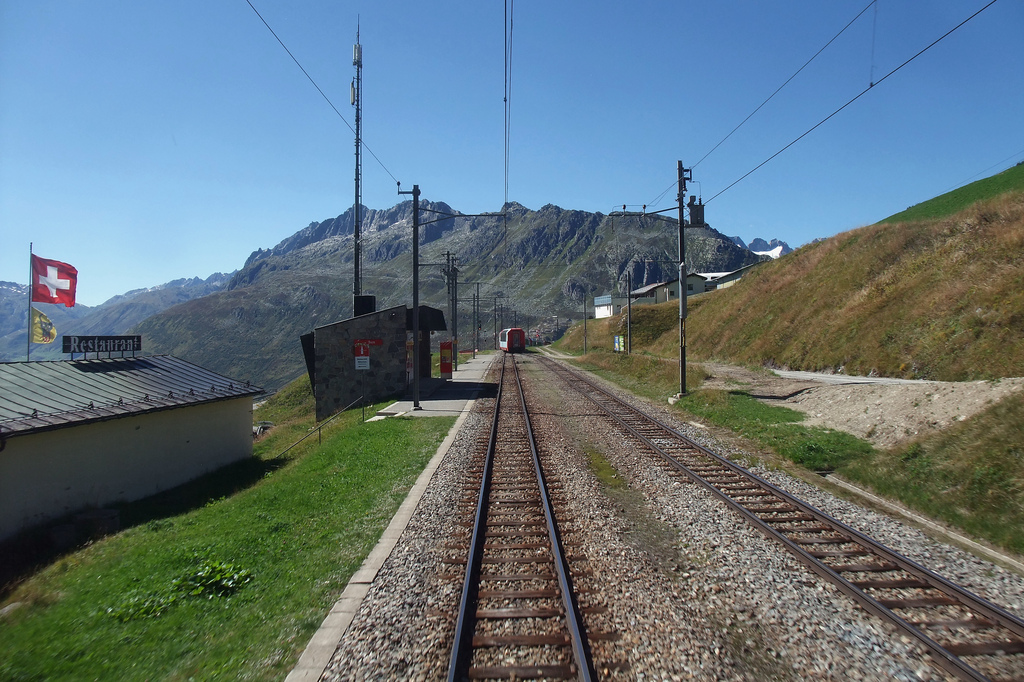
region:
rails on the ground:
[398, 359, 948, 669]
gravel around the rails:
[337, 371, 992, 681]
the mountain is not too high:
[107, 160, 759, 424]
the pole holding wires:
[650, 140, 721, 401]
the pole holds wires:
[324, 17, 392, 302]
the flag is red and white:
[12, 230, 89, 383]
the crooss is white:
[21, 245, 98, 319]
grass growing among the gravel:
[550, 401, 710, 580]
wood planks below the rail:
[420, 363, 616, 667]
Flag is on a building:
[7, 228, 106, 364]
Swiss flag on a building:
[20, 229, 84, 363]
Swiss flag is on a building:
[16, 229, 97, 365]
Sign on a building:
[52, 326, 161, 364]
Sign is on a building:
[49, 324, 155, 367]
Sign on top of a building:
[59, 320, 154, 366]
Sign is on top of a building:
[51, 317, 165, 365]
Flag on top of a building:
[17, 232, 94, 368]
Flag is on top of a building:
[11, 232, 92, 369]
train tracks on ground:
[432, 340, 606, 680]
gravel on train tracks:
[575, 461, 822, 680]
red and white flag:
[19, 258, 89, 304]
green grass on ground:
[63, 523, 292, 680]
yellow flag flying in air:
[8, 305, 65, 353]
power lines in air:
[678, 2, 988, 200]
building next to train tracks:
[0, 349, 273, 533]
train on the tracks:
[489, 324, 534, 359]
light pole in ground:
[385, 175, 436, 384]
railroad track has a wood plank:
[447, 553, 588, 570]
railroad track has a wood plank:
[428, 664, 612, 680]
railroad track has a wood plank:
[430, 626, 618, 646]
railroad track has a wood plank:
[436, 607, 604, 623]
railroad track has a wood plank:
[905, 638, 1023, 661]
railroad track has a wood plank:
[845, 597, 986, 617]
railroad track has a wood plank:
[738, 506, 827, 519]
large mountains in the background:
[0, 199, 754, 371]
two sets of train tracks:
[419, 350, 1021, 680]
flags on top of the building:
[25, 244, 82, 363]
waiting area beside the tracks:
[302, 303, 496, 408]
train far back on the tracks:
[493, 323, 528, 355]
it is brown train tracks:
[468, 347, 566, 680]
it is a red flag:
[22, 241, 73, 337]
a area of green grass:
[28, 426, 463, 671]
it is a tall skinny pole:
[650, 152, 702, 394]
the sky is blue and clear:
[3, 4, 1005, 314]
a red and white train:
[490, 326, 536, 356]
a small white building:
[0, 331, 275, 547]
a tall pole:
[331, 29, 392, 352]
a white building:
[584, 275, 712, 318]